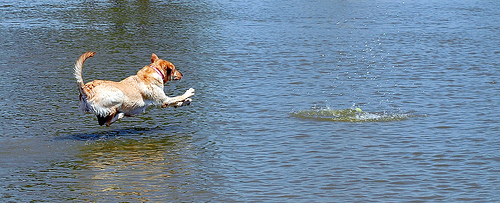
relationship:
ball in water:
[354, 106, 362, 113] [0, 0, 500, 202]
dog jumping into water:
[72, 47, 196, 127] [0, 0, 500, 202]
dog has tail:
[72, 47, 196, 127] [73, 49, 96, 86]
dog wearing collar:
[72, 47, 196, 127] [150, 63, 168, 86]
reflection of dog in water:
[50, 122, 179, 163] [0, 0, 500, 202]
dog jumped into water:
[72, 47, 196, 127] [0, 0, 500, 202]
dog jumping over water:
[72, 47, 196, 127] [0, 0, 500, 202]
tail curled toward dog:
[73, 49, 96, 86] [72, 47, 196, 127]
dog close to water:
[72, 47, 196, 127] [0, 0, 500, 202]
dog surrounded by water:
[72, 47, 196, 127] [0, 0, 500, 202]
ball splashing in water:
[354, 106, 362, 113] [0, 0, 500, 202]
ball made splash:
[354, 106, 362, 113] [287, 77, 412, 124]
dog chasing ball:
[72, 47, 196, 127] [354, 106, 362, 113]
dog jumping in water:
[72, 47, 196, 127] [0, 0, 500, 202]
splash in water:
[287, 77, 412, 124] [0, 0, 500, 202]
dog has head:
[72, 47, 196, 127] [150, 52, 182, 84]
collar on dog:
[150, 63, 168, 86] [72, 47, 196, 127]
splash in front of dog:
[287, 77, 412, 124] [72, 47, 196, 127]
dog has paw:
[72, 47, 196, 127] [186, 82, 195, 98]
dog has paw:
[72, 47, 196, 127] [181, 98, 192, 108]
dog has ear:
[72, 47, 196, 127] [164, 62, 176, 74]